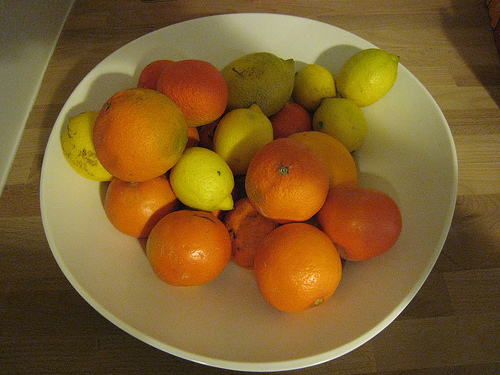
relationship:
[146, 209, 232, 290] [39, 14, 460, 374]
orange on plate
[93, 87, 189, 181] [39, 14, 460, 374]
orange on plate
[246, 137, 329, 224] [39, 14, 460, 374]
orange on plate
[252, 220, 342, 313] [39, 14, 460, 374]
orange on plate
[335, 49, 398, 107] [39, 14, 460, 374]
lemon on plate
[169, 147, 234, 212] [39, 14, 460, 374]
lemon on plate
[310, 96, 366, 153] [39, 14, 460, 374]
lemon on plate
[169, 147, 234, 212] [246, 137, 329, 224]
lemon by orange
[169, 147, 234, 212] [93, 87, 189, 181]
lemon by orange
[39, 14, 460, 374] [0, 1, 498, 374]
plate on table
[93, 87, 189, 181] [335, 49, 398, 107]
orange by lemon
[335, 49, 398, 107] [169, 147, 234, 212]
lemon by lemon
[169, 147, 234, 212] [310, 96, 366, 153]
lemon by lemon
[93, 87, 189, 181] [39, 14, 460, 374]
orange in plate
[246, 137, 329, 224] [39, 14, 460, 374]
orange in plate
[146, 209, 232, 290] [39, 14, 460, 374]
orange in plate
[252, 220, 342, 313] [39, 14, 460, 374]
orange in plate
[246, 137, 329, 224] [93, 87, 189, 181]
orange by orange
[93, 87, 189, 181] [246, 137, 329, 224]
orange by orange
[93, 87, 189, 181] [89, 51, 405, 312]
orange lying in group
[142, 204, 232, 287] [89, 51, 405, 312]
orange lying in group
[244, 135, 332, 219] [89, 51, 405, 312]
orange lying in group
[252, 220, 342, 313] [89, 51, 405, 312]
orange lying in group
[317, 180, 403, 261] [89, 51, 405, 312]
orange lying in group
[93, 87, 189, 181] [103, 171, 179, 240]
orange lying on top of orange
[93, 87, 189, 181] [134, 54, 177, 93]
orange lying on top of orange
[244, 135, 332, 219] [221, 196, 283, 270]
orange lying on top of orange